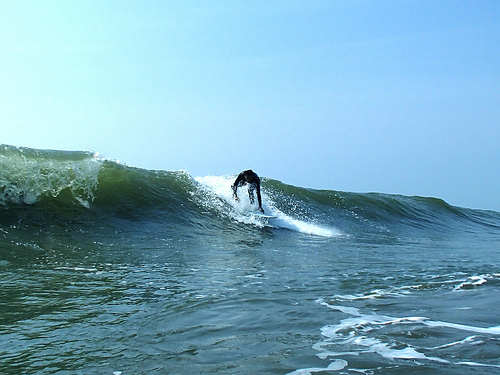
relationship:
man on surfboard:
[232, 169, 265, 214] [247, 206, 276, 219]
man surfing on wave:
[232, 169, 265, 214] [1, 142, 500, 239]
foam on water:
[288, 273, 500, 375] [0, 142, 499, 375]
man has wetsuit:
[232, 169, 265, 214] [232, 170, 264, 206]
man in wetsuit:
[232, 169, 265, 214] [232, 170, 264, 206]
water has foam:
[0, 142, 499, 375] [288, 273, 500, 375]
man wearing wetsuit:
[232, 169, 265, 214] [232, 170, 264, 206]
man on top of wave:
[232, 169, 265, 214] [1, 142, 500, 239]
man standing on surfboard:
[232, 169, 265, 214] [247, 206, 276, 219]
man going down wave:
[232, 169, 265, 214] [1, 142, 500, 239]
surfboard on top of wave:
[247, 206, 276, 219] [1, 142, 500, 239]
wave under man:
[1, 142, 500, 239] [232, 169, 265, 214]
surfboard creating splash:
[247, 206, 276, 219] [199, 174, 349, 239]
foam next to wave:
[288, 273, 500, 375] [1, 142, 500, 239]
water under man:
[0, 142, 499, 375] [232, 169, 265, 214]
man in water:
[232, 169, 265, 214] [0, 142, 499, 375]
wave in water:
[1, 142, 500, 239] [0, 142, 499, 375]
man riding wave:
[232, 169, 265, 214] [1, 142, 500, 239]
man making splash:
[232, 169, 265, 214] [199, 174, 349, 239]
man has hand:
[232, 169, 265, 214] [257, 206, 265, 215]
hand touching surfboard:
[257, 206, 265, 215] [247, 206, 276, 219]